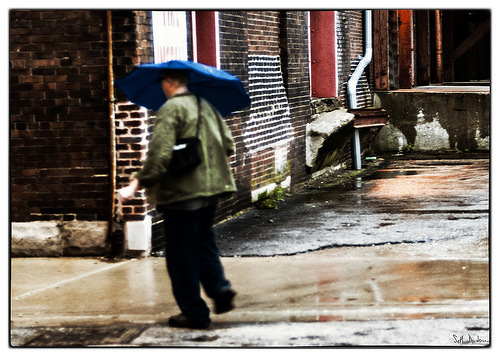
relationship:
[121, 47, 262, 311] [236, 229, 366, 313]
woman walking down sidewalk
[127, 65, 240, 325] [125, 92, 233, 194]
woman in jacket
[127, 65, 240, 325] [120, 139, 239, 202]
woman carrying purse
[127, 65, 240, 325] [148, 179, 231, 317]
woman wearing pants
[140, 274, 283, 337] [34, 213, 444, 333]
shoe on ground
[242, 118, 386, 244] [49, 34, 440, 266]
plant next to building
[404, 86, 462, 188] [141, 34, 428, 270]
patch on wall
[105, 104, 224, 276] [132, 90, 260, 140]
bag on shoulder